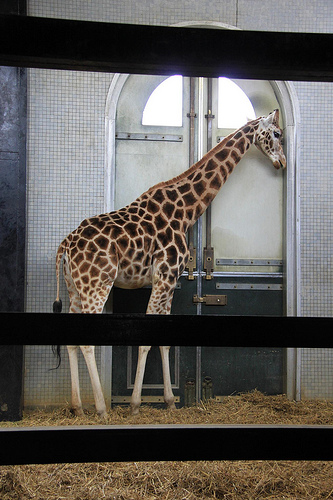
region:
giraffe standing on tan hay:
[52, 103, 287, 417]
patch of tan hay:
[193, 466, 273, 497]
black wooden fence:
[2, 304, 330, 470]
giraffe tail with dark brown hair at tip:
[44, 243, 67, 372]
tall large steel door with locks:
[95, 15, 302, 411]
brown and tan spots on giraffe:
[138, 210, 177, 237]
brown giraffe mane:
[148, 121, 258, 190]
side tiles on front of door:
[52, 133, 84, 180]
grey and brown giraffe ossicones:
[264, 106, 283, 125]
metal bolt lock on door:
[188, 245, 232, 310]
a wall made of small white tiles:
[45, 79, 99, 218]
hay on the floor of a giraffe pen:
[3, 393, 328, 499]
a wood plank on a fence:
[2, 419, 332, 462]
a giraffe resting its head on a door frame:
[245, 104, 299, 175]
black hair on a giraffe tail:
[44, 298, 67, 377]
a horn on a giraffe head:
[274, 107, 281, 126]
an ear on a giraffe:
[262, 108, 276, 125]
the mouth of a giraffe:
[274, 156, 287, 167]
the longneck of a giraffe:
[172, 118, 255, 221]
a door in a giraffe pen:
[109, 25, 287, 410]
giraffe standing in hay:
[52, 105, 287, 421]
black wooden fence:
[1, 315, 331, 461]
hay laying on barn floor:
[1, 389, 332, 498]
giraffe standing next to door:
[51, 108, 288, 424]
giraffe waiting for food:
[51, 108, 285, 417]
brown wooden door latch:
[194, 292, 229, 306]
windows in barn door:
[137, 74, 261, 132]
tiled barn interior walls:
[25, 70, 108, 410]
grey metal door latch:
[116, 128, 187, 143]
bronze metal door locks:
[182, 74, 214, 281]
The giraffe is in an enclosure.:
[26, 98, 305, 420]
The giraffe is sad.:
[215, 101, 301, 184]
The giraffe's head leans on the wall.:
[210, 103, 303, 176]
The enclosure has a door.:
[87, 71, 309, 409]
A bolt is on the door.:
[184, 280, 237, 315]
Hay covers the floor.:
[0, 391, 331, 498]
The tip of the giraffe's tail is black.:
[39, 288, 70, 377]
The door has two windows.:
[132, 77, 276, 135]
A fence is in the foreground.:
[0, 307, 332, 478]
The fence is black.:
[0, 313, 332, 471]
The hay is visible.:
[139, 461, 223, 493]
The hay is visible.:
[155, 425, 261, 492]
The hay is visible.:
[151, 364, 251, 489]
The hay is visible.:
[192, 408, 286, 496]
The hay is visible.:
[201, 414, 253, 479]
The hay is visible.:
[210, 429, 317, 493]